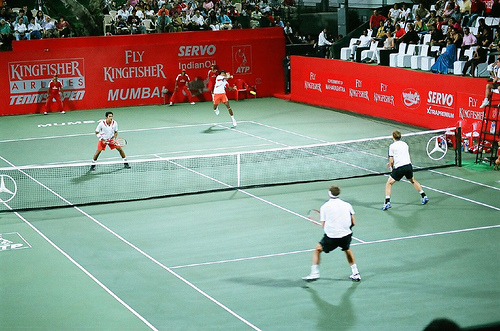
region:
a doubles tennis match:
[32, 3, 491, 329]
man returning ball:
[209, 60, 257, 123]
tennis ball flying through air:
[245, 87, 256, 98]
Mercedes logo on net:
[426, 132, 449, 162]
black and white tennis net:
[2, 142, 453, 205]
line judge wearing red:
[36, 69, 66, 112]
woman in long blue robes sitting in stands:
[431, 37, 458, 72]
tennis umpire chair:
[478, 53, 497, 164]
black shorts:
[318, 234, 353, 251]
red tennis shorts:
[211, 95, 232, 105]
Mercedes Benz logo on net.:
[424, 132, 449, 165]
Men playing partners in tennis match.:
[307, 131, 430, 286]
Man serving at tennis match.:
[210, 69, 239, 127]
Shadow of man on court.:
[295, 254, 370, 329]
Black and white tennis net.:
[20, 139, 375, 211]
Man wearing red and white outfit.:
[90, 111, 137, 170]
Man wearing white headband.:
[325, 186, 345, 199]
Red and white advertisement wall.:
[5, 31, 285, 114]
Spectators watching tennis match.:
[7, 3, 274, 33]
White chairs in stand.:
[389, 43, 429, 70]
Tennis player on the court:
[90, 101, 148, 171]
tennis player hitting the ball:
[201, 43, 257, 123]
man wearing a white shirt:
[319, 199, 364, 242]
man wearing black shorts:
[318, 230, 357, 271]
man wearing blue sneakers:
[378, 187, 395, 221]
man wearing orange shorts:
[203, 89, 245, 106]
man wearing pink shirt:
[459, 35, 478, 47]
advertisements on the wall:
[98, 40, 174, 153]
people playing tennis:
[71, 74, 489, 298]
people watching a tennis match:
[386, 25, 465, 72]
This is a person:
[305, 172, 365, 292]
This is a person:
[371, 111, 441, 227]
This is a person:
[211, 68, 251, 139]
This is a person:
[34, 64, 94, 126]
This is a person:
[160, 58, 193, 108]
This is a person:
[188, 67, 211, 104]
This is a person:
[153, 9, 202, 60]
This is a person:
[52, 13, 82, 62]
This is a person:
[414, 30, 458, 78]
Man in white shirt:
[76, 100, 142, 178]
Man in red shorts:
[75, 106, 149, 184]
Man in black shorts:
[286, 175, 378, 295]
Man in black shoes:
[72, 97, 145, 175]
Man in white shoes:
[289, 180, 374, 299]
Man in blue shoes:
[370, 120, 441, 224]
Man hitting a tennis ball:
[189, 45, 274, 135]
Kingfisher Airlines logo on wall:
[0, 50, 95, 112]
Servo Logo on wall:
[167, 32, 232, 89]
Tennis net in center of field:
[1, 108, 473, 220]